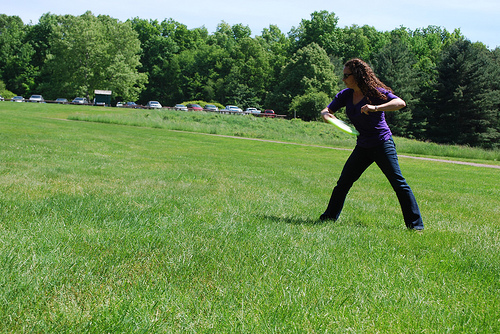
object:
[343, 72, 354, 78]
glasses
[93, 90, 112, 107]
shed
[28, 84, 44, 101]
car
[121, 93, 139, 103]
car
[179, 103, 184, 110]
car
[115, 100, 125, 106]
car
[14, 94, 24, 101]
car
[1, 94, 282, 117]
cars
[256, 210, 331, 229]
shadow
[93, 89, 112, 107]
rest room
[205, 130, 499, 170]
path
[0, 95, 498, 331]
field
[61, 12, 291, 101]
green trees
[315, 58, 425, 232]
girl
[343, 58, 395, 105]
curly hair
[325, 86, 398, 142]
purple shirt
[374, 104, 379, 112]
watch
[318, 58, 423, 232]
man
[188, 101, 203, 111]
car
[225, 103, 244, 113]
car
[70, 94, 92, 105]
car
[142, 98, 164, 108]
car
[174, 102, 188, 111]
car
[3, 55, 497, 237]
game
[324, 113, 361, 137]
zebra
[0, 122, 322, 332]
grass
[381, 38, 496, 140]
pine trees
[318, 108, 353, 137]
frisbee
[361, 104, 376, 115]
hand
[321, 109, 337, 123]
hand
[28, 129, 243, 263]
grassy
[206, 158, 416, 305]
ground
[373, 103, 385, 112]
wrist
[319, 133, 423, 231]
jeans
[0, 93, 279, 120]
parking lot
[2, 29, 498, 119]
background